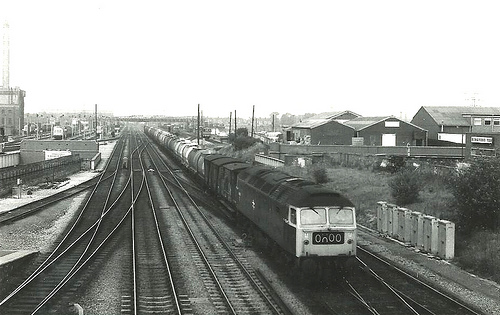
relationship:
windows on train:
[304, 211, 350, 225] [145, 123, 355, 264]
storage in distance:
[291, 118, 415, 156] [11, 6, 488, 137]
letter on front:
[298, 235, 347, 249] [294, 191, 356, 258]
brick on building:
[5, 108, 18, 122] [4, 93, 24, 140]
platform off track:
[13, 168, 94, 218] [128, 147, 163, 308]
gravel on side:
[363, 234, 483, 303] [345, 85, 496, 300]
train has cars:
[145, 123, 355, 264] [152, 122, 276, 211]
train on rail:
[145, 123, 355, 264] [95, 167, 233, 308]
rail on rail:
[95, 167, 233, 308] [95, 167, 233, 308]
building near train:
[4, 93, 24, 140] [145, 123, 355, 264]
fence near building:
[6, 165, 78, 180] [4, 93, 24, 140]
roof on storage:
[418, 108, 486, 122] [291, 118, 415, 156]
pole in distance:
[188, 103, 210, 141] [11, 6, 488, 137]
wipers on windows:
[309, 210, 349, 217] [304, 211, 350, 225]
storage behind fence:
[291, 118, 415, 156] [314, 141, 457, 155]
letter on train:
[298, 235, 347, 249] [145, 123, 355, 264]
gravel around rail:
[363, 234, 483, 303] [95, 167, 233, 308]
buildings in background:
[12, 81, 489, 160] [11, 6, 488, 137]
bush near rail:
[447, 154, 499, 205] [95, 167, 233, 308]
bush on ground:
[447, 154, 499, 205] [291, 138, 499, 256]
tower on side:
[0, 84, 38, 151] [7, 4, 84, 228]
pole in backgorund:
[188, 103, 210, 141] [11, 6, 488, 137]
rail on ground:
[95, 167, 233, 308] [55, 155, 250, 308]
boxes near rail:
[372, 198, 464, 254] [95, 167, 233, 308]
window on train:
[282, 202, 302, 223] [145, 123, 355, 264]